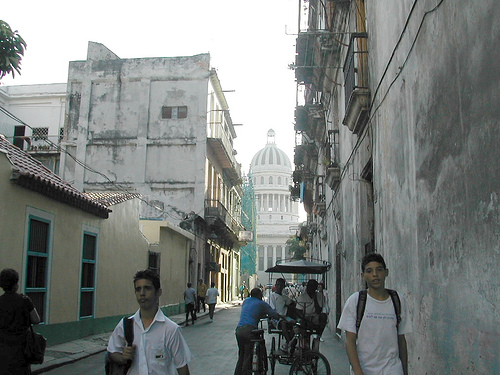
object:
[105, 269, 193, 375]
boy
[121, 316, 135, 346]
backpack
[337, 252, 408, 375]
boy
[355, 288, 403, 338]
backpack